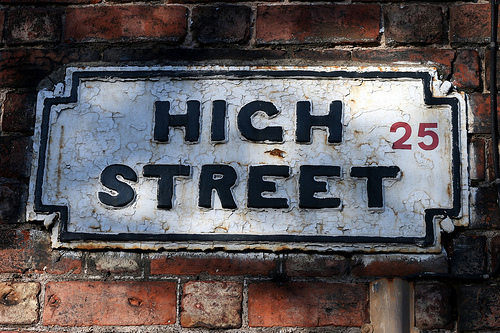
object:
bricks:
[0, 0, 497, 333]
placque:
[25, 65, 470, 252]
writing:
[97, 99, 439, 211]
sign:
[25, 62, 470, 255]